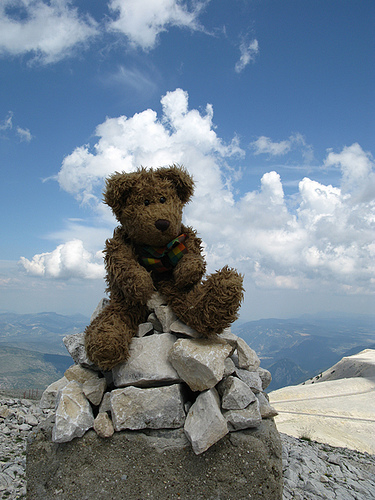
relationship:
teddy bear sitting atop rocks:
[83, 162, 244, 373] [38, 290, 279, 460]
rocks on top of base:
[38, 290, 279, 460] [26, 404, 282, 498]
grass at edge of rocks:
[295, 423, 316, 445] [274, 429, 375, 499]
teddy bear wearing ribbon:
[83, 162, 244, 373] [131, 233, 189, 273]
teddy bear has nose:
[83, 162, 244, 373] [152, 217, 174, 235]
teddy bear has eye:
[83, 162, 244, 373] [142, 194, 150, 207]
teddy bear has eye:
[83, 162, 244, 373] [158, 194, 166, 206]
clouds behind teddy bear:
[17, 239, 106, 285] [83, 162, 244, 373]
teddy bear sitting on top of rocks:
[83, 162, 244, 373] [38, 290, 279, 460]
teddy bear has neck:
[83, 162, 244, 373] [116, 222, 189, 246]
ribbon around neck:
[131, 233, 189, 273] [116, 222, 189, 246]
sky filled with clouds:
[1, 0, 374, 318] [3, 1, 374, 296]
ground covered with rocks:
[1, 390, 374, 499] [1, 395, 374, 499]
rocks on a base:
[38, 290, 279, 460] [26, 404, 282, 498]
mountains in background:
[1, 311, 374, 404] [0, 0, 374, 404]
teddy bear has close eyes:
[83, 162, 244, 373] [140, 192, 166, 209]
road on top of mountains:
[2, 337, 374, 360] [1, 311, 374, 404]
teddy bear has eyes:
[83, 162, 244, 373] [140, 192, 166, 209]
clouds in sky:
[3, 1, 374, 296] [1, 0, 374, 318]